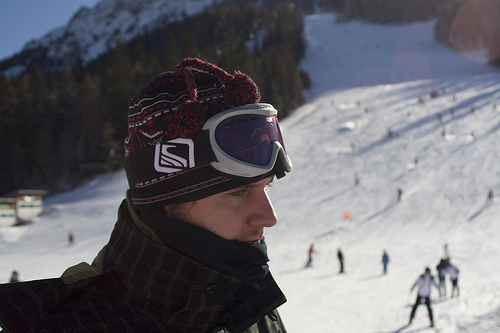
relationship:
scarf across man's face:
[120, 208, 280, 304] [160, 139, 285, 251]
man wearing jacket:
[1, 54, 293, 332] [3, 207, 294, 329]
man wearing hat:
[1, 54, 293, 332] [120, 57, 292, 205]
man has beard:
[1, 54, 293, 332] [230, 226, 266, 250]